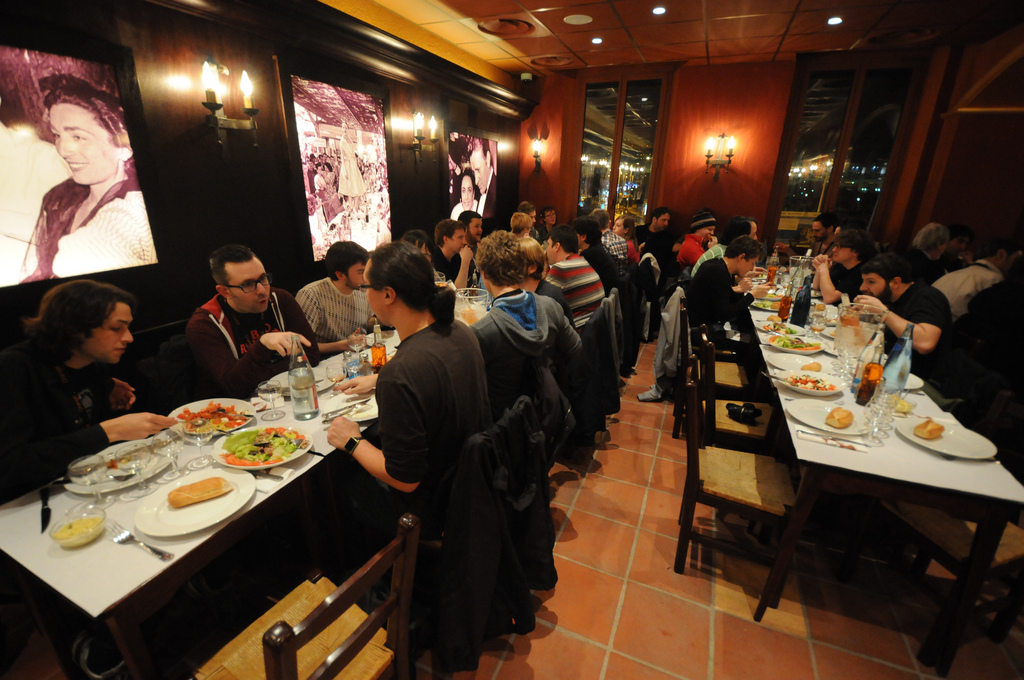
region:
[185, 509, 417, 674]
A wood chair in a restaurant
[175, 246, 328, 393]
A man wearing glasses seated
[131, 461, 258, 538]
An oblong plate sitting on table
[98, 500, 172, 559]
Silverware laying on table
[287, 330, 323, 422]
A bottle sitting on a table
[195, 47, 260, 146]
Lights on a wall in a restaurant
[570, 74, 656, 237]
Windows in a restaurant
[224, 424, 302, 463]
Food on a plate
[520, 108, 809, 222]
white lights on wall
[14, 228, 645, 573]
many people sitting at table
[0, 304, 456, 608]
long and white table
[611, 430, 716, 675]
floor is dark orange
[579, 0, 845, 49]
white and recessed lights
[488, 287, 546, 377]
boy has blue and grey hoodie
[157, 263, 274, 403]
man has red hoodie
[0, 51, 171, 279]
Black and white photo of a woman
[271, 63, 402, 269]
Large black and white photo on wall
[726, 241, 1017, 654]
Long dining table with white cover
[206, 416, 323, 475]
Plate of green and orange food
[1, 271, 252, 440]
Woman getting food from a plate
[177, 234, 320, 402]
Man sitting at a dining table touching a glass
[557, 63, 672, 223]
Two large reflective windows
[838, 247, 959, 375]
Man eating food at the table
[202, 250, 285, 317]
the head of a man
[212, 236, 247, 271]
the hair of a man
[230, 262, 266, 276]
the forehead of a man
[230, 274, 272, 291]
the glasses of a man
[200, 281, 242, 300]
the ear of a man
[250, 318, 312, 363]
the hand of a man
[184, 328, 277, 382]
the arm of a man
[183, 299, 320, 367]
the jacket of a man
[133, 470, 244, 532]
a plate that is white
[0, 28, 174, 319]
framed black and white picture of a woman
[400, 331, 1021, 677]
square terracotta colored floor tiles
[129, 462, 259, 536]
plate with a piece of bread on it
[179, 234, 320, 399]
man wearing a maroon hoodie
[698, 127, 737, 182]
decorative wall lights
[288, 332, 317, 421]
clear bottle filled with a clear liquid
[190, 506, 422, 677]
brown wooden chair with a woven seat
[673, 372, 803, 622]
brown wooden chair with a woven seat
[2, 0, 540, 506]
dark wood paneled wall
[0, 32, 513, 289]
art decor depicting people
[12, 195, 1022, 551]
whole bunch of people sharing meal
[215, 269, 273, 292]
glasses on man's face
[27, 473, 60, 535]
butter knife laying on table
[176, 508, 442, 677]
one of several empty dining chairs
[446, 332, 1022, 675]
floor covered in tile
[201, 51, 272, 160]
one of several sconce lamps affixed to wall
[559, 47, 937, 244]
long narrow windows for looking outside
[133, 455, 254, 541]
white plate with loaf of bread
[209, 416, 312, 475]
white plate full of salad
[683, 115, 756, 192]
A light on the wall is turned on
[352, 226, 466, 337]
Black hair in a ponytail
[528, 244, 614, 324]
Stripes on a shirt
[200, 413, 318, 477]
A plate full of food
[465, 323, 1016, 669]
Brown tiles on the floor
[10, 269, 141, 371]
A guy has brown hair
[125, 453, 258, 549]
Bread on a white plate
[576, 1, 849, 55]
Three ceiling lights are turned on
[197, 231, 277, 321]
Man is wearing glasses